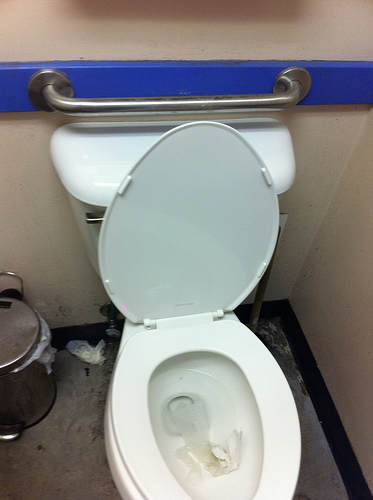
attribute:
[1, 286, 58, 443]
can — Silver 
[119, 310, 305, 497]
seat — Downed 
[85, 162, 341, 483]
toilet — White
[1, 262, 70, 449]
trash can — Silver 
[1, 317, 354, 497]
floor — Dirty 